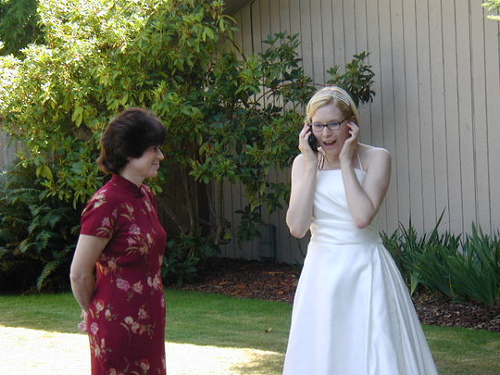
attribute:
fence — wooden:
[162, 4, 498, 261]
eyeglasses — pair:
[302, 117, 342, 137]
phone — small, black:
[293, 121, 321, 135]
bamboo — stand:
[191, 169, 251, 238]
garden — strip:
[409, 228, 499, 299]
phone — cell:
[301, 112, 322, 152]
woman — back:
[69, 109, 167, 373]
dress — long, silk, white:
[291, 166, 396, 367]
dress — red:
[92, 185, 174, 273]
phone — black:
[305, 126, 322, 157]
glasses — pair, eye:
[307, 120, 347, 138]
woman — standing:
[66, 104, 186, 373]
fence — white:
[356, 56, 493, 180]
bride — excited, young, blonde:
[280, 81, 436, 373]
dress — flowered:
[66, 172, 171, 374]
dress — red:
[74, 173, 176, 373]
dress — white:
[282, 149, 447, 372]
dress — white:
[278, 166, 438, 373]